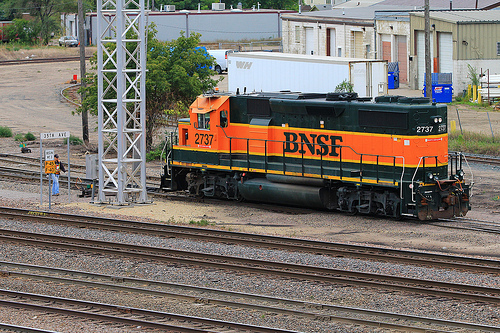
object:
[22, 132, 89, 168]
sign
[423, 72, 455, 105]
dumpster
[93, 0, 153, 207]
structure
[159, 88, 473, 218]
train car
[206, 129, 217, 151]
boy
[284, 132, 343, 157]
logo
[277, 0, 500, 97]
building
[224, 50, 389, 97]
trailer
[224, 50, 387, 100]
truck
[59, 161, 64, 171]
arm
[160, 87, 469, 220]
car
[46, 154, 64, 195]
person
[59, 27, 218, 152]
tree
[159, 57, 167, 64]
leaves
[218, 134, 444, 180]
hand rails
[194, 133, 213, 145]
number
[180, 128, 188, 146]
door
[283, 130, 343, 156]
black words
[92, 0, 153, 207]
tower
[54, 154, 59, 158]
cap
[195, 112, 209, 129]
window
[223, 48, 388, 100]
cargo container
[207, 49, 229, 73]
van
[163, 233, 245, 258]
gravel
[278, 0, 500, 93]
garage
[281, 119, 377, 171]
train body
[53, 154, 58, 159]
head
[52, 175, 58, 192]
legs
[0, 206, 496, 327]
rail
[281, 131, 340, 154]
characters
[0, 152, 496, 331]
bunch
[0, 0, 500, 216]
background